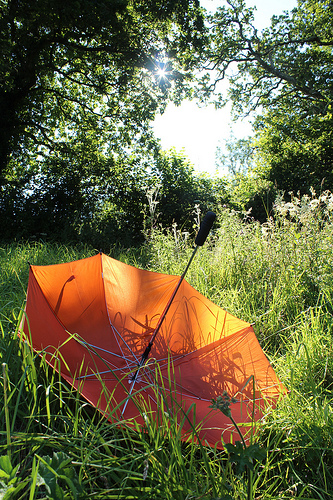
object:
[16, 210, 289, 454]
umbrella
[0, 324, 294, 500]
grass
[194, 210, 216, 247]
handle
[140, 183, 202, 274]
weeds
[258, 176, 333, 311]
weeds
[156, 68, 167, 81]
sun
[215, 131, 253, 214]
trees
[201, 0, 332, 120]
trees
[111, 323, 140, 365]
support wire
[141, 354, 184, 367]
support wire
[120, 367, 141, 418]
support wire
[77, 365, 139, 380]
support wire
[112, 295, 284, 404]
silhouette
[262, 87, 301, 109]
tree branch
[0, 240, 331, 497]
field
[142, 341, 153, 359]
plastic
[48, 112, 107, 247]
tree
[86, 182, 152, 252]
tree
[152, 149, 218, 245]
tree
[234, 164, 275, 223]
tree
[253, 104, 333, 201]
tree